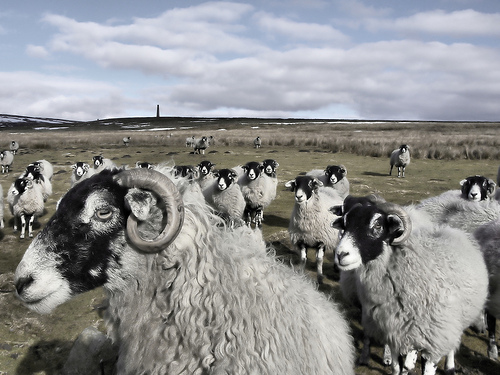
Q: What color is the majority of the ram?
A: White.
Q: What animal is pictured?
A: Sheep.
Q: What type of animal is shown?
A: Sheep.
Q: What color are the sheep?
A: Gray.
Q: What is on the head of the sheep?
A: Horns.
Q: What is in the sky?
A: Clouds.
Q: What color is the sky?
A: Blue.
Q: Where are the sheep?
A: Field.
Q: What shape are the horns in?
A: Curved.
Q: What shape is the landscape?
A: Flat.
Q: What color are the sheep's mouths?
A: White.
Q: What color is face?
A: Black.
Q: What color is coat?
A: Gray.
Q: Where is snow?
A: On ground.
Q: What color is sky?
A: Blue.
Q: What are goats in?
A: Herd.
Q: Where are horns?
A: On goat.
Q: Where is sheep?
A: Near camera.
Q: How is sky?
A: Cloudy.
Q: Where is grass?
A: In field.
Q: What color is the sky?
A: Blue and white.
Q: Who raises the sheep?
A: The farmer.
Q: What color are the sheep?
A: Grey.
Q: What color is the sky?
A: Grey and cloudy.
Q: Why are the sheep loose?
A: They are in pasture.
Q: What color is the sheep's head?
A: Black and white.